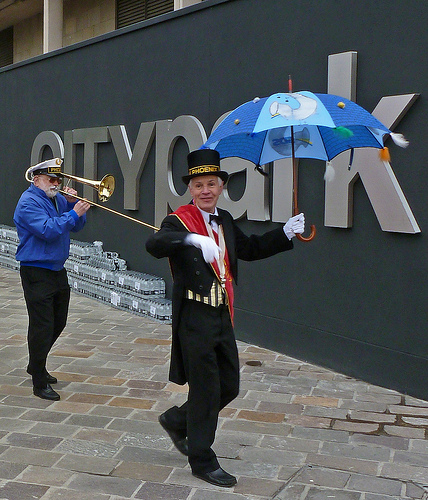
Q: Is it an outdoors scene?
A: Yes, it is outdoors.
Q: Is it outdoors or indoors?
A: It is outdoors.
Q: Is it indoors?
A: No, it is outdoors.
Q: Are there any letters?
A: Yes, there are letters.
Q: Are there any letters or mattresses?
A: Yes, there are letters.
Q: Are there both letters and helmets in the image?
A: No, there are letters but no helmets.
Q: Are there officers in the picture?
A: No, there are no officers.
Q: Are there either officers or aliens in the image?
A: No, there are no officers or aliens.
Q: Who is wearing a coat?
A: The man is wearing a coat.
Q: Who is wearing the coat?
A: The man is wearing a coat.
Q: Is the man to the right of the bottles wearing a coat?
A: Yes, the man is wearing a coat.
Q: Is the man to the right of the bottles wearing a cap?
A: No, the man is wearing a coat.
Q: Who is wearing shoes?
A: The man is wearing shoes.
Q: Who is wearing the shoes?
A: The man is wearing shoes.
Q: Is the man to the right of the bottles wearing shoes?
A: Yes, the man is wearing shoes.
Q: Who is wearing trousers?
A: The man is wearing trousers.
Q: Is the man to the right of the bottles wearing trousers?
A: Yes, the man is wearing trousers.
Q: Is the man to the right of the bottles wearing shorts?
A: No, the man is wearing trousers.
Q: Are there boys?
A: No, there are no boys.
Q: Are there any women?
A: No, there are no women.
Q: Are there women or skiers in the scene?
A: No, there are no women or skiers.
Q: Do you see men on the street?
A: Yes, there is a man on the street.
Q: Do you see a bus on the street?
A: No, there is a man on the street.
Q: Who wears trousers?
A: The man wears trousers.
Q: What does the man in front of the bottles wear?
A: The man wears pants.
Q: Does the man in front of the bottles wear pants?
A: Yes, the man wears pants.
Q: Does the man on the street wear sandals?
A: No, the man wears pants.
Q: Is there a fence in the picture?
A: No, there are no fences.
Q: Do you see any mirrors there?
A: No, there are no mirrors.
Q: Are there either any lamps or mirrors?
A: No, there are no mirrors or lamps.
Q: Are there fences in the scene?
A: No, there are no fences.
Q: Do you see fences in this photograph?
A: No, there are no fences.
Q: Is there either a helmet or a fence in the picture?
A: No, there are no fences or helmets.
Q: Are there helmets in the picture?
A: No, there are no helmets.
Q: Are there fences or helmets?
A: No, there are no helmets or fences.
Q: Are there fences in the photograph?
A: No, there are no fences.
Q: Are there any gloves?
A: Yes, there are gloves.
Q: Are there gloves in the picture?
A: Yes, there are gloves.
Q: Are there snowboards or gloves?
A: Yes, there are gloves.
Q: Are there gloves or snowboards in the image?
A: Yes, there are gloves.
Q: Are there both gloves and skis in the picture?
A: No, there are gloves but no skis.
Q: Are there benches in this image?
A: No, there are no benches.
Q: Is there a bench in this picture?
A: No, there are no benches.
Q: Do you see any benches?
A: No, there are no benches.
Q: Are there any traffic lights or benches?
A: No, there are no benches or traffic lights.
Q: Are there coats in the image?
A: Yes, there is a coat.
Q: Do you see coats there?
A: Yes, there is a coat.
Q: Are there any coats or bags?
A: Yes, there is a coat.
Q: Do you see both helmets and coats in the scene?
A: No, there is a coat but no helmets.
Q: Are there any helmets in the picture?
A: No, there are no helmets.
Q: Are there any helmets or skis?
A: No, there are no helmets or skis.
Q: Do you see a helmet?
A: No, there are no helmets.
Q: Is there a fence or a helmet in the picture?
A: No, there are no helmets or fences.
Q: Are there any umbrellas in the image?
A: Yes, there is an umbrella.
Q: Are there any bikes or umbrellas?
A: Yes, there is an umbrella.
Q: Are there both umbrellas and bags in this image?
A: No, there is an umbrella but no bags.